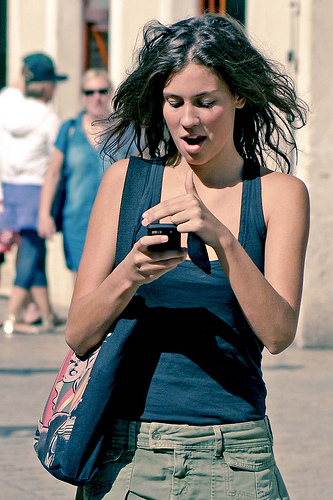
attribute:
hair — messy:
[114, 58, 170, 166]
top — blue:
[158, 283, 282, 432]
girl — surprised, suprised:
[126, 59, 239, 170]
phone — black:
[145, 215, 192, 295]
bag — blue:
[84, 334, 131, 499]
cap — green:
[21, 63, 68, 88]